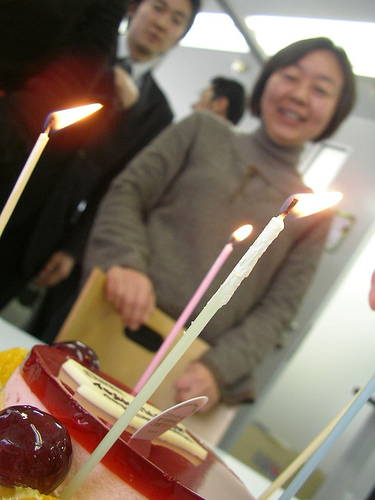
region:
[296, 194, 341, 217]
fire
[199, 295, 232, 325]
a white candle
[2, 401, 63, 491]
a red cherry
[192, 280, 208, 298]
a pink candle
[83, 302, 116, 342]
a brown chair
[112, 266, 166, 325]
women has hand on chair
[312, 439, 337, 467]
a blue candle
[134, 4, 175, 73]
a person standing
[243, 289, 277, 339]
women is wearing a grey sweater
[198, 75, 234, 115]
a man standing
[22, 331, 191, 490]
This is a cake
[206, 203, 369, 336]
These are candles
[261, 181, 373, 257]
These are lit candles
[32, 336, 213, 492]
This is made of jello and is red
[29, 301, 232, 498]
This is a strawberry cake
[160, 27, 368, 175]
This is a woman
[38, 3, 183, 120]
This is a a man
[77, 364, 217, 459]
This is a message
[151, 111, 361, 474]
This is a gray shirt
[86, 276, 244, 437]
This is a wooden chair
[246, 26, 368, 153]
The woman has short black hair.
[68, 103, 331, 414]
The woman is wearing a grey sweater.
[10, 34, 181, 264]
The man is wearing a black suit jacket.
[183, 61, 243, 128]
The side of a man's head.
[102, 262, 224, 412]
The woman's hands are resting on the chair.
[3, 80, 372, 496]
A birthday cake with candles.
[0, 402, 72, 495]
A cherry on the cake.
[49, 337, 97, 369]
Another cherry is partially visible.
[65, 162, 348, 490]
A yellow candle on the cake.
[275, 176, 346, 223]
The flame of a candle.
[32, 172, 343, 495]
two candles with flames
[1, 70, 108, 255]
white candle with flame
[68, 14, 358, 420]
Asian woman smiling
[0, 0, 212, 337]
Asian man in suit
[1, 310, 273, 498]
pink and red dessert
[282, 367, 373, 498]
part of a blue candle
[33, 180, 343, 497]
long, thin candle with orange flame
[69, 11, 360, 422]
woman holding onto chair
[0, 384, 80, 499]
red, round, shiny piece of dessert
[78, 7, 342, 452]
woman with short hair cut wearing gray top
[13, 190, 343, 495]
cake with tall candles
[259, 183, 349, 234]
flame on top of candle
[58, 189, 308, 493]
pink and white candles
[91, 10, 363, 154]
people looking at cake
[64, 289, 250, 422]
woman with her hands on back of chair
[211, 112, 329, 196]
women wearing a turtleneck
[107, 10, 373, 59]
lights on ceiling above people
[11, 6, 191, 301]
man wearing a black suit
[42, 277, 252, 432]
light brown wooden chair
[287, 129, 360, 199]
window in the plain white wall